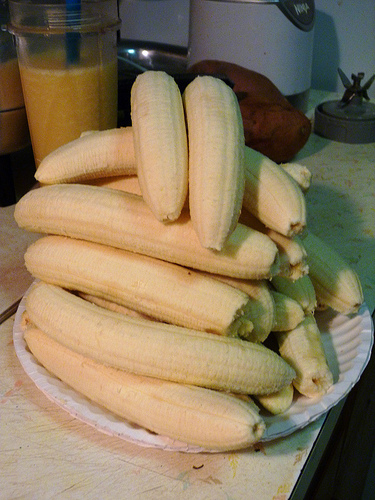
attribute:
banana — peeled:
[30, 121, 309, 241]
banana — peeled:
[11, 180, 282, 282]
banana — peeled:
[126, 65, 187, 226]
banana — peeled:
[18, 282, 300, 396]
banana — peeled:
[103, 103, 307, 292]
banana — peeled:
[10, 184, 271, 267]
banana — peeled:
[183, 70, 251, 258]